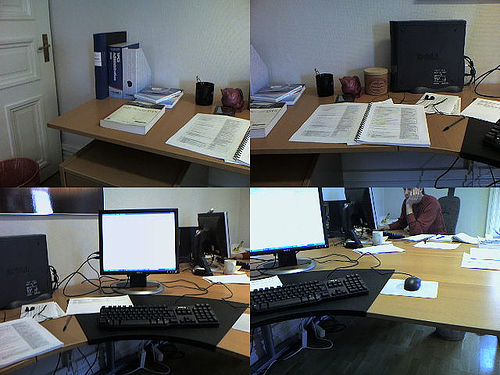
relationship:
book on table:
[292, 101, 431, 146] [250, 86, 500, 166]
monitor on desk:
[98, 209, 180, 276] [2, 247, 250, 372]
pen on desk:
[62, 316, 74, 331] [2, 247, 250, 372]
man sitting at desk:
[379, 187, 447, 235] [250, 226, 499, 334]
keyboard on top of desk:
[99, 304, 218, 326] [2, 247, 250, 372]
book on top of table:
[292, 101, 431, 146] [250, 86, 500, 166]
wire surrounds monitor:
[162, 281, 208, 302] [98, 209, 180, 276]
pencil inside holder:
[313, 68, 319, 74] [315, 73, 335, 97]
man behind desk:
[379, 187, 447, 235] [250, 226, 499, 334]